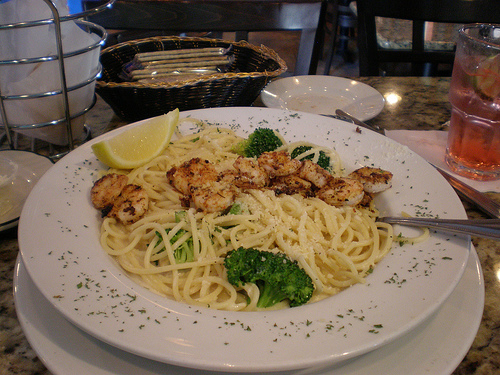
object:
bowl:
[17, 106, 472, 373]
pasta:
[95, 117, 428, 312]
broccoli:
[230, 127, 283, 158]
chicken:
[90, 173, 149, 227]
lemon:
[91, 108, 180, 170]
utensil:
[374, 217, 500, 241]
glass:
[445, 23, 500, 182]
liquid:
[445, 53, 500, 170]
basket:
[93, 35, 288, 122]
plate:
[260, 75, 386, 124]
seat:
[356, 0, 500, 77]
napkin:
[382, 128, 498, 193]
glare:
[385, 93, 399, 105]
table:
[1, 75, 500, 375]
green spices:
[29, 108, 457, 354]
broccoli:
[146, 127, 330, 308]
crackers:
[117, 47, 236, 83]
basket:
[0, 1, 114, 160]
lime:
[472, 53, 500, 101]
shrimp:
[90, 151, 393, 225]